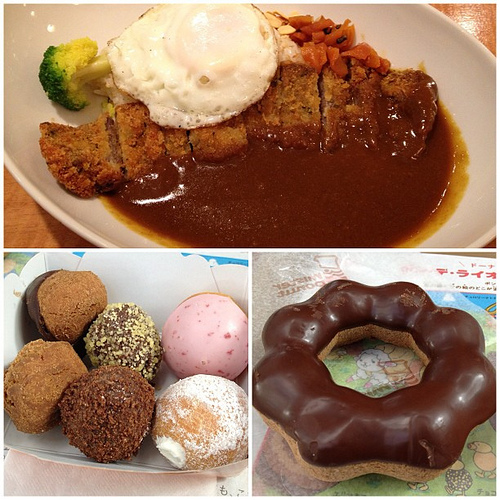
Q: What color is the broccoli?
A: Green.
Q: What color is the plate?
A: White.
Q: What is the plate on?
A: The table.